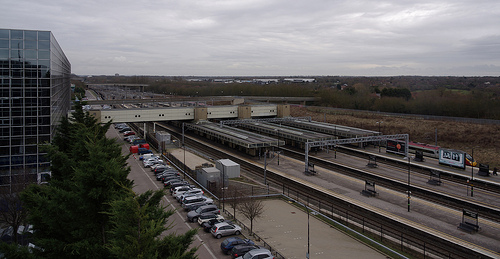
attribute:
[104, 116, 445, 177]
station — empty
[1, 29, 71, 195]
building — glass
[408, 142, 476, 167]
train — white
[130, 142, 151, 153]
car — parked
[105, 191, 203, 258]
tree — green, tall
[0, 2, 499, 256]
day — cloudy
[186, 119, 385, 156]
terminals — three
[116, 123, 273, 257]
row — long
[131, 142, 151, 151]
container — red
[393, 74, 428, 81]
hill — short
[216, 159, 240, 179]
container — for cargo